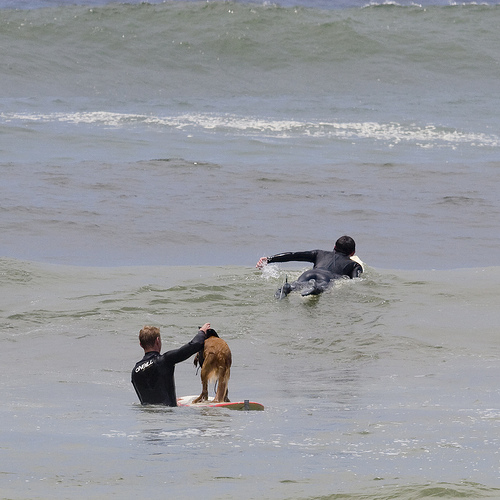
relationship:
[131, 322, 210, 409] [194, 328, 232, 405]
man and dog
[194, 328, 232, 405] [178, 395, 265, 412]
dog riding on surfboard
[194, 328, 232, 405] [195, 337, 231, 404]
dog with fur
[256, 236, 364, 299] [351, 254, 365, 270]
man laying on surfboard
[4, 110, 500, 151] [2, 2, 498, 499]
wave moving in ocean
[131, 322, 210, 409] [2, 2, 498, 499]
man standing in ocean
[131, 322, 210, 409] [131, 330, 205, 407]
man wearing wet suit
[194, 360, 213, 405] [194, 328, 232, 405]
leg of dog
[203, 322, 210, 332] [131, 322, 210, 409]
hand of man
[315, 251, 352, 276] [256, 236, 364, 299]
back of man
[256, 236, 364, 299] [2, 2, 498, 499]
man surfing at ocean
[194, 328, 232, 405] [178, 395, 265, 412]
dog standing on surfboard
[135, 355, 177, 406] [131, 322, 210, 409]
torso of man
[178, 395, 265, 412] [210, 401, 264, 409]
surfboard with stripe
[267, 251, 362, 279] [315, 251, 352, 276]
shirt on back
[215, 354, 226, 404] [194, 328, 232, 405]
tail of dog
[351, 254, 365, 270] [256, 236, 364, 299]
surfboard used by man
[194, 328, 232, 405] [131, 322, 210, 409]
dog being held up by man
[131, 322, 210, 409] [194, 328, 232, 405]
man holding dog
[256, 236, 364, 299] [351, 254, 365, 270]
man paddling out on surfboard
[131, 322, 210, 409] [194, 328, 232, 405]
man surfing with dog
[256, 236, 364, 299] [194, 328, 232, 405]
man surfing with dog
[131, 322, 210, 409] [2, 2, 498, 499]
man in ocean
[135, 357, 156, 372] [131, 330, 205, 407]
name of brand on back of wet suit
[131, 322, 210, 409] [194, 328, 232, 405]
man holds dog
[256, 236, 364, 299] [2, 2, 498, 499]
man paddling through ocean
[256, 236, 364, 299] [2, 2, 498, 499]
man surfing in ocean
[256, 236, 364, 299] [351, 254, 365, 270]
man lies on surfboard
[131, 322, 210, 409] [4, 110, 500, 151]
man riding wave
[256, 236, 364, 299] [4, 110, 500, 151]
man riding wave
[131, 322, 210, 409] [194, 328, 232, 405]
man teaches surfing to dog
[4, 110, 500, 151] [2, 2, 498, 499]
wave of ocean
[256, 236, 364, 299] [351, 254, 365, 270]
man on surfboard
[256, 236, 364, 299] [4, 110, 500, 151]
man swimming out towards wave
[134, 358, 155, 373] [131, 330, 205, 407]
white letters on back of wet suit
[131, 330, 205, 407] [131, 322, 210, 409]
wet suit worn by man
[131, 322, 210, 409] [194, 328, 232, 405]
man standing next to dog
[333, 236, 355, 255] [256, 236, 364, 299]
hair of man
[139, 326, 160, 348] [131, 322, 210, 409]
hair of man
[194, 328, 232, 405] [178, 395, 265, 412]
dog on surfboard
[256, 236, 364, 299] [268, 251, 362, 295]
man wearing wet suit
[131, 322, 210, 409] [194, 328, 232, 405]
man with hand on dog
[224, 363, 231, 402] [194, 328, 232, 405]
leg of dog